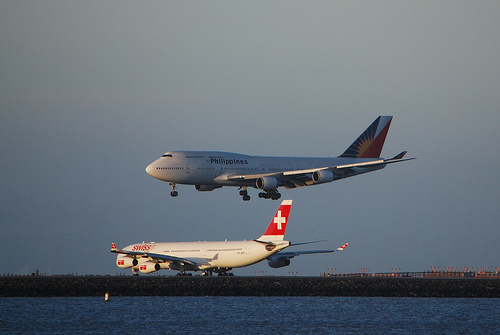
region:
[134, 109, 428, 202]
Airplane in the air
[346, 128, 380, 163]
Yellow sun in vertical stabilizer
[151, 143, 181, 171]
Cockpit of plane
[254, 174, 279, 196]
Engine in front of wing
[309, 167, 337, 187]
Engine back wing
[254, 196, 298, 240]
White cross on vertical stabilizer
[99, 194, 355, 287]
White plane flying above ocean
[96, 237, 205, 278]
Left wing of plane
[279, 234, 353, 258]
Right wing of plane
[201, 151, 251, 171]
Letter on plane says Philippines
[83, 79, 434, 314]
two passenger planes are landing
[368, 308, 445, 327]
blue water at airport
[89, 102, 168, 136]
the sky is cloudy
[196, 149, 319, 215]
the word is Philippines.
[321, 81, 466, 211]
the tail of the plane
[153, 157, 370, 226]
plane is going to land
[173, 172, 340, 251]
the plane has wheels down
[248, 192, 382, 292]
the logo is swiss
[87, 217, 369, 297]
the plane is swiss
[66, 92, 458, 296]
two international airplanes crossing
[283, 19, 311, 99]
The sky is a rather dark blue-grey color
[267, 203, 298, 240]
There is a white cross surrounded by red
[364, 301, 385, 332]
The water is brown-green in its coloring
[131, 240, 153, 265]
The word on this airplane is SWISS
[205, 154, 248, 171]
The brand of the higher aircraft is Philippines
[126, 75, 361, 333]
This photo was taken in the early evening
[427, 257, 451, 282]
There are orange barriers that are clearly visible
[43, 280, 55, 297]
This coast is rather rocky in its texture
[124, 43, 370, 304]
Jess took this picture when he was traveling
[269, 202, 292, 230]
white cross on the tail of the plane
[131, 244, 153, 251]
swiss the name of the airline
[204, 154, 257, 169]
phillippienes is the name of this airline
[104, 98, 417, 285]
one plane is flying over the other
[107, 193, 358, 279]
plane is sitting on the runway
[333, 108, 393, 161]
the tail of this plane is blue white yellow and red in color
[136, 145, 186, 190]
the nose on this plane is lighter because the sun is hitting it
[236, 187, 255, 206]
the landing gear is down and ready for the landing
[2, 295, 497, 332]
the ocean is right next to the runway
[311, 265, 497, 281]
red fence on the other side of the runway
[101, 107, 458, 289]
Two planes in the air.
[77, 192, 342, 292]
The lower plane is white.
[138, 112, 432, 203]
The higher plane is silver.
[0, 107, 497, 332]
Planes flying over water.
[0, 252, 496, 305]
Rocky coast in the background.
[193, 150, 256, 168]
The plane's company is Philippines.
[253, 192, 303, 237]
Red and white cross on the tail.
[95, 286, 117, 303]
One buoy in the water.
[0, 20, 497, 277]
The sky is gray.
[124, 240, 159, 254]
White plane is owned by Swiss.